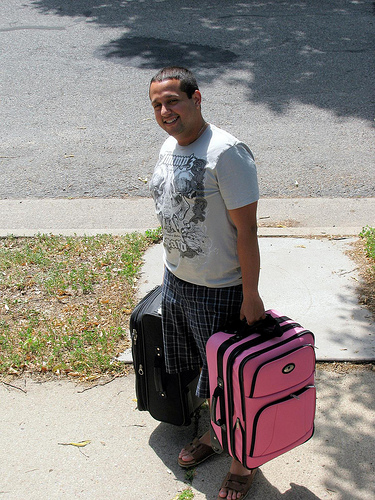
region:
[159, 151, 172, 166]
white letter on shirt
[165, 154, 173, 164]
white letter on shirt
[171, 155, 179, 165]
white letter on shirt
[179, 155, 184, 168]
white letter on shirt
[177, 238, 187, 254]
white letter on shirt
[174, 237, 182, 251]
white letter on shirt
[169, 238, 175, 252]
white letter on shirt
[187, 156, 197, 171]
white letter on shirt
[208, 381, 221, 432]
black colored suitcase handle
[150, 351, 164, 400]
black colored suitcase handle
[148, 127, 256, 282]
Man wearing a grey shirt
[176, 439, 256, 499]
Man wearing brown sandals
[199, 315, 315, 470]
Man holding a pink suitcase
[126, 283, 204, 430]
Man holding a black suitcase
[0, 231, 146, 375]
Grass in a yard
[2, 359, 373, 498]
Sidewalk under a man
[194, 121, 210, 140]
Gold chain on a man's neck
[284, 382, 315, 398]
Two zippers on a pink suitcase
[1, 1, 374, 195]
Street behind a man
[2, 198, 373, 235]
Curb on a street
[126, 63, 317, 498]
Man carrying two suitcases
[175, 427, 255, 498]
Sandals on man's feet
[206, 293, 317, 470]
Pink suitcase in man's hand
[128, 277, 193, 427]
Black suitcase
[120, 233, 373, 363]
Concrete slab between the grass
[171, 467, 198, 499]
Grass growing between the concrete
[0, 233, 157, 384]
Patchy grass along the sidewalk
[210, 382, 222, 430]
Black handle on the pink suitcase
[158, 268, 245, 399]
Plaid shorts on man's legs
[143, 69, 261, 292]
Smiling man in a grey t-shirt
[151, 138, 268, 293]
gray graphic tee shirt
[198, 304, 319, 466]
pink and black suitcase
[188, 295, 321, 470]
left hand carrying pink and black suitcase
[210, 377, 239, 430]
black handle of pink and black suitcase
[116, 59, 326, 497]
man carrying two suitcases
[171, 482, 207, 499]
grass growing in crack in sidewalk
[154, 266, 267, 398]
blue and white plaid shorts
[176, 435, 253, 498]
leather sandals on two feet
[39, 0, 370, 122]
shadow of tree leaves on asphalt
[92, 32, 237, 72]
black asphalt patch on gray road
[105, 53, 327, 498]
guy carrying two suitcases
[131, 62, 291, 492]
guy wearing black plaid shorts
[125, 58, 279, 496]
guy wearing sandals with bare feet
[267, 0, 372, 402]
sidewalk, curb, and road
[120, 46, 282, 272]
guy wearing gray t-shirt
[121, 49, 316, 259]
guy with dark hair smiling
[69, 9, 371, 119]
black patch on road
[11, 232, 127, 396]
green and brown grass in dirt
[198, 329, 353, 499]
black handle on pink suitcase